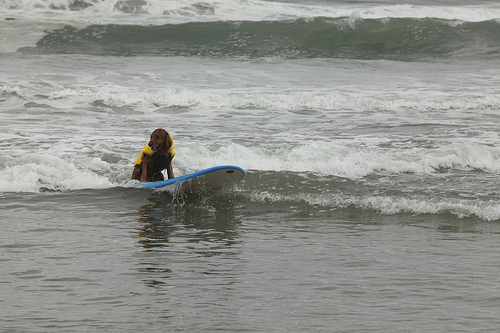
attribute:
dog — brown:
[130, 126, 177, 184]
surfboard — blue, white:
[119, 163, 247, 203]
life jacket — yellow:
[132, 137, 177, 167]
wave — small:
[0, 53, 500, 221]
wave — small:
[0, 2, 499, 63]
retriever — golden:
[129, 128, 177, 184]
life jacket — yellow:
[132, 132, 178, 167]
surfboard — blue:
[131, 162, 245, 204]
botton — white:
[124, 168, 243, 204]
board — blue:
[130, 162, 246, 196]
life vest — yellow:
[134, 140, 176, 162]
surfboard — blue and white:
[139, 161, 246, 198]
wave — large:
[44, 9, 468, 66]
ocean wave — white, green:
[2, 13, 483, 66]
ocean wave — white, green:
[169, 168, 485, 225]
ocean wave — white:
[2, 81, 484, 112]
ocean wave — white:
[1, 84, 484, 117]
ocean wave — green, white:
[219, 166, 485, 219]